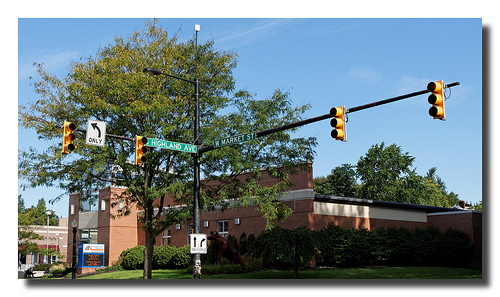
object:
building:
[69, 165, 483, 275]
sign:
[190, 234, 210, 255]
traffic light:
[63, 119, 78, 154]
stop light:
[65, 122, 75, 131]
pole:
[192, 79, 204, 277]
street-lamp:
[70, 220, 77, 278]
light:
[329, 107, 342, 119]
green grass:
[45, 267, 484, 280]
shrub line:
[121, 224, 474, 269]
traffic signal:
[328, 105, 346, 141]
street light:
[141, 67, 163, 76]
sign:
[82, 243, 105, 267]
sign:
[85, 119, 107, 146]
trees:
[19, 17, 320, 279]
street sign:
[142, 138, 198, 156]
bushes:
[117, 244, 190, 269]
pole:
[74, 127, 141, 142]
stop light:
[137, 135, 149, 144]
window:
[224, 221, 231, 232]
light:
[426, 79, 440, 94]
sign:
[212, 131, 256, 148]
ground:
[21, 277, 486, 284]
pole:
[200, 80, 460, 152]